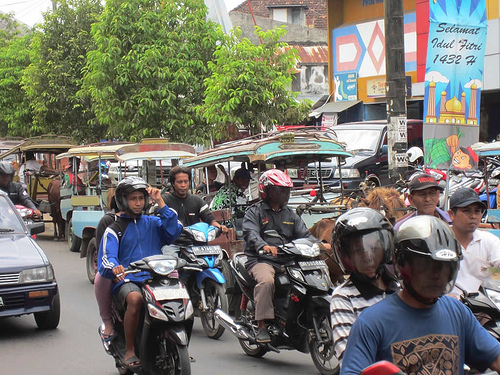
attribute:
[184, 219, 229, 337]
scooter — blue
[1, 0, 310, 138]
trees — green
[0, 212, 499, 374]
steet — congested, dry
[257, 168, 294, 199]
grapic — red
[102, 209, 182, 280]
jacket — blue, black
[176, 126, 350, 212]
bus — rusty, blue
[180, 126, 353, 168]
top — green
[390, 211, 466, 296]
helmet — black, silver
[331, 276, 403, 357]
top — black, striped, white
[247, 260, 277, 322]
pants — khaki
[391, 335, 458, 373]
design — tan, gold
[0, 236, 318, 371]
street — crowded, grey, clear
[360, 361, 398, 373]
handle — pink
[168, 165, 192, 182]
curly hair — black, short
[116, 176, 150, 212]
helmet — black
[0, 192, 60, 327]
car — blue, gray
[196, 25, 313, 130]
tree — small, green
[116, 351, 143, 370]
flip flops — black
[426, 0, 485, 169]
banner — blue, large square, green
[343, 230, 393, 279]
visor — down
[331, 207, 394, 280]
helmet — black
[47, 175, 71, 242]
horse — brown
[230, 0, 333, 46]
walls — brown